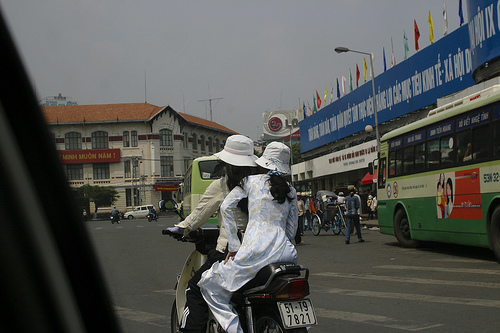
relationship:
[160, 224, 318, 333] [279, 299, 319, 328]
bike has plate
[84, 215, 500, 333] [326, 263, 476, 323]
road has crosswalk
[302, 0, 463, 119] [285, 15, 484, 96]
flags on roof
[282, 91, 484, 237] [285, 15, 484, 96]
building has roof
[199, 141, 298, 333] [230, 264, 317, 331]
people riding motorcycle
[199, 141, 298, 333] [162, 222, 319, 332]
people riding motorcycle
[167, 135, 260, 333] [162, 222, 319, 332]
people riding motorcycle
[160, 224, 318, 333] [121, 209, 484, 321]
bike on road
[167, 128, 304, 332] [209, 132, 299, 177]
people wearing hats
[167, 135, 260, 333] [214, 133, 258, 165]
people wearing hat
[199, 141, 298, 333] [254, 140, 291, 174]
people wearing hat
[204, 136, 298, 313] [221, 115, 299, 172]
people wearing hats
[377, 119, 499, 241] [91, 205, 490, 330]
bus on road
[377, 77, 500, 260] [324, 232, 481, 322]
bus on street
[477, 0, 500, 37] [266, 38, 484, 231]
flags on top of building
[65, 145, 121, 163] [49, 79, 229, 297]
plaque on side of building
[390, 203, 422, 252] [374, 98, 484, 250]
tire on bus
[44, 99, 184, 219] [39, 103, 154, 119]
building has roof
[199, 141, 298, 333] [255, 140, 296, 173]
people with hat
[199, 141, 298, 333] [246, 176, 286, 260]
people with dress